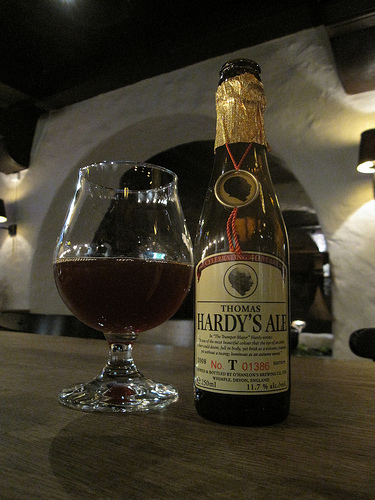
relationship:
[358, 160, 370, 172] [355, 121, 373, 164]
lightbulb in lamp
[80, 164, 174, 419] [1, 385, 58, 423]
glass on table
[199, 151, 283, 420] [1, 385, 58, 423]
bottle on table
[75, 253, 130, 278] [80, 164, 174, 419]
wine in glass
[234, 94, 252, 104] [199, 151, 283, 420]
foil on bottle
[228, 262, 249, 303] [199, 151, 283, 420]
picture on bottle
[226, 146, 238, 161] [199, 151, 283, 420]
string on bottle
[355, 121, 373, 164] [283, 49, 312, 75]
lamp on wall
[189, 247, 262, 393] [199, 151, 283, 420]
label on bottle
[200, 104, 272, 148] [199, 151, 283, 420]
neck of bottle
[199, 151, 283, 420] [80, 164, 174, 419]
bottle next to glass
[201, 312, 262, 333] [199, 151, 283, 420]
logo on bottle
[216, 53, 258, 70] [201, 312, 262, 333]
bottlecap on logo